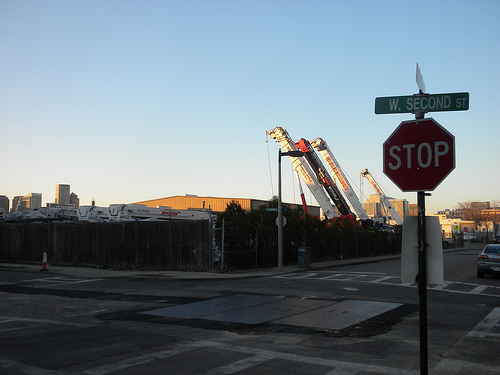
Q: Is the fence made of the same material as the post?
A: No, the fence is made of wood and the post is made of metal.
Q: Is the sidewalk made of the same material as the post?
A: No, the sidewalk is made of concrete and the post is made of metal.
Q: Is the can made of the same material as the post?
A: No, the can is made of plastic and the post is made of metal.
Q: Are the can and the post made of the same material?
A: No, the can is made of plastic and the post is made of metal.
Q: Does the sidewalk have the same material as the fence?
A: No, the sidewalk is made of concrete and the fence is made of wood.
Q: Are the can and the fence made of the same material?
A: No, the can is made of plastic and the fence is made of wood.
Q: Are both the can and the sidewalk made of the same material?
A: No, the can is made of plastic and the sidewalk is made of concrete.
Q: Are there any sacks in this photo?
A: No, there are no sacks.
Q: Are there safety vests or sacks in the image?
A: No, there are no sacks or safety vests.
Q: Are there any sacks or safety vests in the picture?
A: No, there are no sacks or safety vests.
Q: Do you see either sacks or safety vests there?
A: No, there are no sacks or safety vests.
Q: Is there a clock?
A: No, there are no clocks.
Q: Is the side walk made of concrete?
A: Yes, the side walk is made of concrete.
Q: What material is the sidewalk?
A: The sidewalk is made of concrete.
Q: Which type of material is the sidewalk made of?
A: The sidewalk is made of concrete.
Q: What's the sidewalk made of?
A: The sidewalk is made of concrete.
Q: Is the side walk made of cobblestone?
A: No, the side walk is made of cement.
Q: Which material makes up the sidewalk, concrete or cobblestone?
A: The sidewalk is made of concrete.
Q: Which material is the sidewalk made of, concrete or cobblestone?
A: The sidewalk is made of concrete.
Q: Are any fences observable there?
A: Yes, there is a fence.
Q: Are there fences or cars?
A: Yes, there is a fence.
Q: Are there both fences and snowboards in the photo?
A: No, there is a fence but no snowboards.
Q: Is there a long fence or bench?
A: Yes, there is a long fence.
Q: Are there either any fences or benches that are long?
A: Yes, the fence is long.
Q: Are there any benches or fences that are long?
A: Yes, the fence is long.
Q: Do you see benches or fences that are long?
A: Yes, the fence is long.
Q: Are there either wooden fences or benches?
A: Yes, there is a wood fence.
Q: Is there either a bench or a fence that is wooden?
A: Yes, the fence is wooden.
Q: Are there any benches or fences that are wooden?
A: Yes, the fence is wooden.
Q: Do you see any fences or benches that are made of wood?
A: Yes, the fence is made of wood.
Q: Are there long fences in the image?
A: Yes, there is a long fence.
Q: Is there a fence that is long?
A: Yes, there is a fence that is long.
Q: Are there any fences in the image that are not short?
A: Yes, there is a long fence.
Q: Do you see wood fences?
A: Yes, there is a wood fence.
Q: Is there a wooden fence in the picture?
A: Yes, there is a wood fence.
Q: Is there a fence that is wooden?
A: Yes, there is a fence that is wooden.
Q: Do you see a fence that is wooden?
A: Yes, there is a fence that is wooden.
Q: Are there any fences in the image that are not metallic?
A: Yes, there is a wooden fence.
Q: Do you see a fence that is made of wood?
A: Yes, there is a fence that is made of wood.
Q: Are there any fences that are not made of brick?
A: Yes, there is a fence that is made of wood.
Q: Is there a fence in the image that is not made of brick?
A: Yes, there is a fence that is made of wood.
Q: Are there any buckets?
A: No, there are no buckets.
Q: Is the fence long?
A: Yes, the fence is long.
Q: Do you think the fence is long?
A: Yes, the fence is long.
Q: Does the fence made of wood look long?
A: Yes, the fence is long.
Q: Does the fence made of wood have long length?
A: Yes, the fence is long.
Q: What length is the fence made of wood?
A: The fence is long.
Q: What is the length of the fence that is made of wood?
A: The fence is long.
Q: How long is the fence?
A: The fence is long.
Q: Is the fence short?
A: No, the fence is long.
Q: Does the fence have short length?
A: No, the fence is long.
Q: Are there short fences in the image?
A: No, there is a fence but it is long.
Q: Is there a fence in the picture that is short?
A: No, there is a fence but it is long.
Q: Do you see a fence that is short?
A: No, there is a fence but it is long.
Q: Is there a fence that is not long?
A: No, there is a fence but it is long.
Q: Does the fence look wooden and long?
A: Yes, the fence is wooden and long.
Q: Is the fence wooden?
A: Yes, the fence is wooden.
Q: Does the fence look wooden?
A: Yes, the fence is wooden.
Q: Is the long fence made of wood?
A: Yes, the fence is made of wood.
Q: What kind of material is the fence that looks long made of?
A: The fence is made of wood.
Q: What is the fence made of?
A: The fence is made of wood.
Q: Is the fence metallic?
A: No, the fence is wooden.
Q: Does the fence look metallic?
A: No, the fence is wooden.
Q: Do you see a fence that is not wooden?
A: No, there is a fence but it is wooden.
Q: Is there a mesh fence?
A: No, there is a fence but it is made of wood.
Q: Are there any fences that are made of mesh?
A: No, there is a fence but it is made of wood.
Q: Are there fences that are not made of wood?
A: No, there is a fence but it is made of wood.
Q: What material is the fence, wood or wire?
A: The fence is made of wood.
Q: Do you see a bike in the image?
A: No, there are no bikes.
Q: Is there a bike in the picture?
A: No, there are no bikes.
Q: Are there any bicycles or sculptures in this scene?
A: No, there are no bicycles or sculptures.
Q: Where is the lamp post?
A: The lamp post is on the side walk.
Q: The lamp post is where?
A: The lamp post is on the side walk.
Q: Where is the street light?
A: The lamp post is on the side walk.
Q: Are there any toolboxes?
A: No, there are no toolboxes.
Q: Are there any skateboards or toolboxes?
A: No, there are no toolboxes or skateboards.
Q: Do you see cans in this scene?
A: Yes, there is a can.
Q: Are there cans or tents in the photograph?
A: Yes, there is a can.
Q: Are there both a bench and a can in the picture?
A: No, there is a can but no benches.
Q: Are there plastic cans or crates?
A: Yes, there is a plastic can.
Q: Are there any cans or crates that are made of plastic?
A: Yes, the can is made of plastic.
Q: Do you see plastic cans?
A: Yes, there is a can that is made of plastic.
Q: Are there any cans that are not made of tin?
A: Yes, there is a can that is made of plastic.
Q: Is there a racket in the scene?
A: No, there are no rackets.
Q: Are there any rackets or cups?
A: No, there are no rackets or cups.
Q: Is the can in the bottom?
A: Yes, the can is in the bottom of the image.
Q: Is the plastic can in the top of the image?
A: No, the can is in the bottom of the image.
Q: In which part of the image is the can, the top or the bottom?
A: The can is in the bottom of the image.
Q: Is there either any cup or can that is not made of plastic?
A: No, there is a can but it is made of plastic.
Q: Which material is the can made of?
A: The can is made of plastic.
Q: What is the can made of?
A: The can is made of plastic.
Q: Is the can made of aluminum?
A: No, the can is made of plastic.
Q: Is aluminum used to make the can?
A: No, the can is made of plastic.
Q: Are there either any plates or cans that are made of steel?
A: No, there is a can but it is made of plastic.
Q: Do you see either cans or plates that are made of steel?
A: No, there is a can but it is made of plastic.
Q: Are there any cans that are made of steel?
A: No, there is a can but it is made of plastic.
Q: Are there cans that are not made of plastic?
A: No, there is a can but it is made of plastic.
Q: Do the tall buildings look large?
A: Yes, the buildings are large.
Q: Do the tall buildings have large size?
A: Yes, the buildings are large.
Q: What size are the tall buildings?
A: The buildings are large.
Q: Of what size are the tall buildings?
A: The buildings are large.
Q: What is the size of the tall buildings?
A: The buildings are large.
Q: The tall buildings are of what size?
A: The buildings are large.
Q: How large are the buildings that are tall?
A: The buildings are large.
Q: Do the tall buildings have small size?
A: No, the buildings are large.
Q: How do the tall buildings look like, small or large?
A: The buildings are large.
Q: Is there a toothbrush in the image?
A: No, there are no toothbrushes.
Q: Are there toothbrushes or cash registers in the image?
A: No, there are no toothbrushes or cash registers.